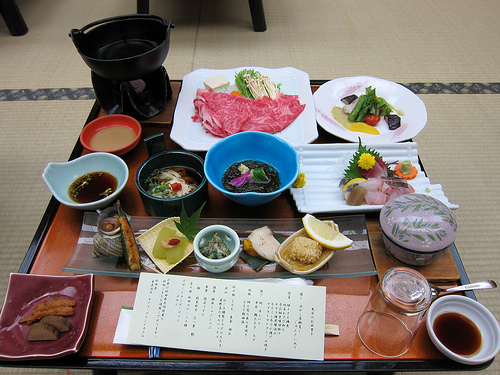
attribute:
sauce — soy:
[39, 164, 134, 208]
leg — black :
[1, 0, 30, 36]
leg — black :
[246, 0, 268, 32]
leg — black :
[136, 0, 152, 27]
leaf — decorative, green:
[168, 196, 201, 239]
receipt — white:
[126, 270, 326, 363]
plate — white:
[295, 68, 432, 150]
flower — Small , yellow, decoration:
[348, 152, 379, 177]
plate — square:
[166, 39, 336, 167]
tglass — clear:
[356, 264, 431, 358]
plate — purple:
[314, 66, 429, 145]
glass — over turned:
[344, 249, 444, 356]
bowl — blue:
[208, 127, 305, 197]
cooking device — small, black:
[39, 2, 206, 125]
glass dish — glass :
[336, 250, 376, 274]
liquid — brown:
[433, 307, 482, 349]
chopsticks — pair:
[323, 322, 343, 339]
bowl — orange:
[40, 149, 141, 221]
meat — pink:
[23, 297, 88, 344]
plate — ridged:
[289, 140, 460, 221]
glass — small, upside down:
[359, 267, 431, 354]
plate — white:
[171, 65, 319, 152]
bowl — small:
[39, 150, 128, 205]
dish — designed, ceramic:
[381, 230, 445, 264]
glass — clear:
[356, 260, 428, 362]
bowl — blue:
[202, 120, 302, 203]